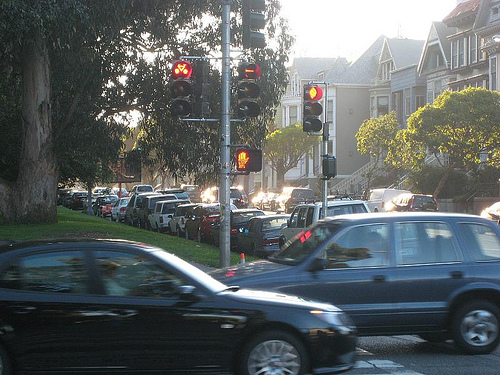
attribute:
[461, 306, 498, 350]
wheel — rear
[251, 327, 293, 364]
wheel — rear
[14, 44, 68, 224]
tree trunk — large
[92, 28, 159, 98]
leaves — many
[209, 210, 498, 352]
suv — small, driving by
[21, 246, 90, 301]
window — car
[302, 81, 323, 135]
traffic light — red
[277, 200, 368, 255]
car — parked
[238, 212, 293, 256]
car — parked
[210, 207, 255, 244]
car — parked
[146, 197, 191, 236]
car — parked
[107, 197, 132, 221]
car — parked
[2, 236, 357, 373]
car — black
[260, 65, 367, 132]
light — traffic, red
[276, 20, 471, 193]
large houses — in back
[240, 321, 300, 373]
wheel — vehicle, one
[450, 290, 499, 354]
wheel — vehicle, one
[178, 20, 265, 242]
signs — lit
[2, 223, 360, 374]
car — black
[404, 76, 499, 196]
tree — large, trunk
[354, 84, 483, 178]
leaves — green